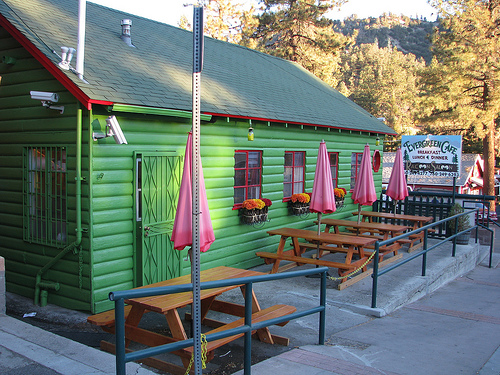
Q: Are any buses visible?
A: No, there are no buses.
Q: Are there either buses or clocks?
A: No, there are no buses or clocks.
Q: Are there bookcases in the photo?
A: No, there are no bookcases.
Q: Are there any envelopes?
A: No, there are no envelopes.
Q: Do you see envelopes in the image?
A: No, there are no envelopes.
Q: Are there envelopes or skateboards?
A: No, there are no envelopes or skateboards.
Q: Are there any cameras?
A: Yes, there is a camera.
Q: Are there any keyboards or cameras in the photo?
A: Yes, there is a camera.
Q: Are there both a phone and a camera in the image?
A: No, there is a camera but no phones.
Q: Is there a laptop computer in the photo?
A: No, there are no laptops.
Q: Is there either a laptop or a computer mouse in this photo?
A: No, there are no laptops or computer mice.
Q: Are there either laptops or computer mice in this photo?
A: No, there are no laptops or computer mice.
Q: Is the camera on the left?
A: Yes, the camera is on the left of the image.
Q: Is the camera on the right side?
A: No, the camera is on the left of the image.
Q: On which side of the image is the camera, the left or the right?
A: The camera is on the left of the image.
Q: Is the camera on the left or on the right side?
A: The camera is on the left of the image.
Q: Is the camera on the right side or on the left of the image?
A: The camera is on the left of the image.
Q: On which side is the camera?
A: The camera is on the left of the image.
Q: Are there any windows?
A: Yes, there is a window.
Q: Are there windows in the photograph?
A: Yes, there is a window.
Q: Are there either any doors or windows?
A: Yes, there is a window.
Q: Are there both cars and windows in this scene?
A: No, there is a window but no cars.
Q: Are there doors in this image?
A: Yes, there is a door.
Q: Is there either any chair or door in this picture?
A: Yes, there is a door.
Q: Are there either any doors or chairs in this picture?
A: Yes, there is a door.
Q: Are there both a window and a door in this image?
A: Yes, there are both a door and a window.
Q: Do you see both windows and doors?
A: Yes, there are both a door and a window.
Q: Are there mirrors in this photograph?
A: No, there are no mirrors.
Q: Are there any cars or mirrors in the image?
A: No, there are no mirrors or cars.